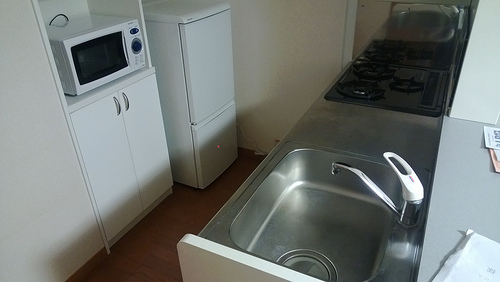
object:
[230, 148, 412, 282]
sink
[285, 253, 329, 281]
hole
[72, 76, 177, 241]
cabinet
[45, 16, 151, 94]
microwave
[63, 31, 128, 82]
door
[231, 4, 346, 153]
wall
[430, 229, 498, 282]
paper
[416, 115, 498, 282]
counter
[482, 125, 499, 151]
paper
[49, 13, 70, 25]
cord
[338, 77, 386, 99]
stove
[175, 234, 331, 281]
edge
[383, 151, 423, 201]
handle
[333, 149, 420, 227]
faucet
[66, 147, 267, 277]
floor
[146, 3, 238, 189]
fridge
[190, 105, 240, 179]
freezer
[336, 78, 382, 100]
grill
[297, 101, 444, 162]
space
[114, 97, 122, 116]
handle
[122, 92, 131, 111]
handle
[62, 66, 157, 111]
shelf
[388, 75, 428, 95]
burners